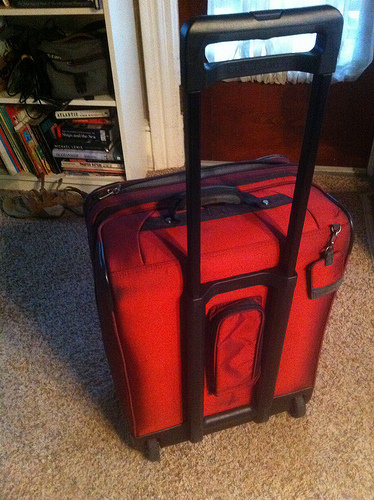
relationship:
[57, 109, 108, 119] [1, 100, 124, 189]
book on shelf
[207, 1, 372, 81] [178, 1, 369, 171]
curtain over door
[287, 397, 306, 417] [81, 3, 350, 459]
wheel on case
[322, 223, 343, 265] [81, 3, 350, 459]
zipper in case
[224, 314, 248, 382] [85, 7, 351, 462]
stain on travel case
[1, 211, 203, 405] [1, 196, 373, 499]
shadow on carpet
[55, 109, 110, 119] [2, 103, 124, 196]
book on shelf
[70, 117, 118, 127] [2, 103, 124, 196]
book on shelf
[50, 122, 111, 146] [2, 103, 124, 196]
book on shelf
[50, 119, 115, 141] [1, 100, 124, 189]
book on shelf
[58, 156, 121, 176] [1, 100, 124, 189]
book on shelf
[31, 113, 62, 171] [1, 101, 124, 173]
book on shelf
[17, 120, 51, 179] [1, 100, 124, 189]
book on shelf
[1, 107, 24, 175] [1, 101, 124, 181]
book on shelf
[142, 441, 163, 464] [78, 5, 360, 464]
wheel of luggage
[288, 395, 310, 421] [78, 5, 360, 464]
wheel of luggage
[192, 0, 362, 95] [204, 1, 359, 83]
window covered with curtain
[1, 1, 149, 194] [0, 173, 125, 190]
bookshelf with shelf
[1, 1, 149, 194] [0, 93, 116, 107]
bookshelf with shelf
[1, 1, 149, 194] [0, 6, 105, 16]
bookshelf with shelf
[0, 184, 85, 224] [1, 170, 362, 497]
sandal on floor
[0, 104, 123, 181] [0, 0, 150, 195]
books on shelf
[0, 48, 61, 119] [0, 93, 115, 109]
wire on shelf